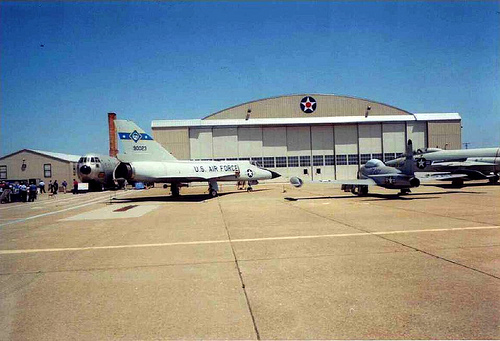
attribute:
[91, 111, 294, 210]
plane — white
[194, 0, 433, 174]
sky — clear, blue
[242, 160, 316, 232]
hangar — large 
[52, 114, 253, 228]
plane — small 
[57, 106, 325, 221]
plane — large 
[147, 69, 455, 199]
building — tan , small 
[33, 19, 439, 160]
sky — blue 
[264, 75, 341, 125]
logo — blue , red , white 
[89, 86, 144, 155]
stripe — blue 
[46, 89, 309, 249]
plane — white 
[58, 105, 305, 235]
plane — white 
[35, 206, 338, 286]
line — white 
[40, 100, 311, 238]
plane — white 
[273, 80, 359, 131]
logo — blue 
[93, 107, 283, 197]
plane — large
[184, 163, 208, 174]
letter — blue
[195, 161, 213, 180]
letter — blue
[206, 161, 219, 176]
letter — blue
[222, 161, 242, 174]
letter — blue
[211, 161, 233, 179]
letter — blue